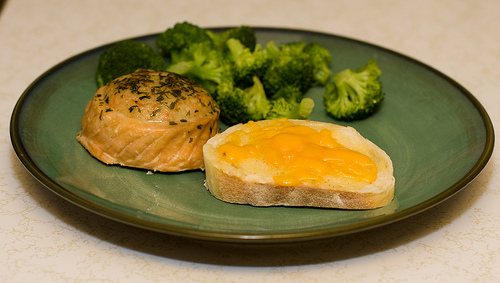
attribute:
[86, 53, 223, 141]
specks — small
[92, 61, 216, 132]
specks — small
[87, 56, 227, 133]
specks — small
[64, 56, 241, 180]
food — piece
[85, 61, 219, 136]
specks — small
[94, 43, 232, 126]
specks — small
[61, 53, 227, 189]
food — piece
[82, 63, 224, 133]
specks — small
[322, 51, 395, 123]
veggie — green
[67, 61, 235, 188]
salmon — piece, sprinkled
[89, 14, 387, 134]
broccoli — pile, boiled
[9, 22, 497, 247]
plate — green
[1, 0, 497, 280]
counter top — white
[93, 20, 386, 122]
broccoli — green